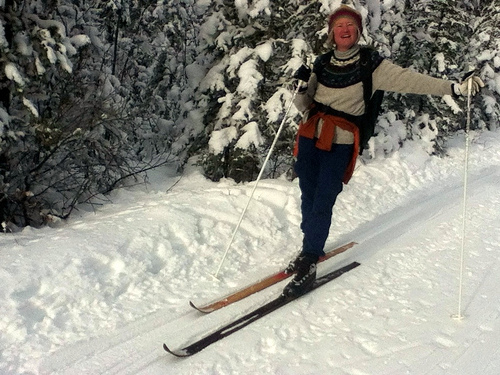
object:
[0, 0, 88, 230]
trees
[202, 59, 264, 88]
snow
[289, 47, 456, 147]
sweater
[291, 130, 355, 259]
pants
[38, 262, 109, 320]
tracks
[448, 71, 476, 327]
ski pole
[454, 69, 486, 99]
hand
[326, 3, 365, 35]
hat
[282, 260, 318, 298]
boots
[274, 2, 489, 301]
woman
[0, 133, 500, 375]
ground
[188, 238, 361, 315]
skis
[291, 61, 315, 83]
glove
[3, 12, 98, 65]
branches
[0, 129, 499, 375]
path